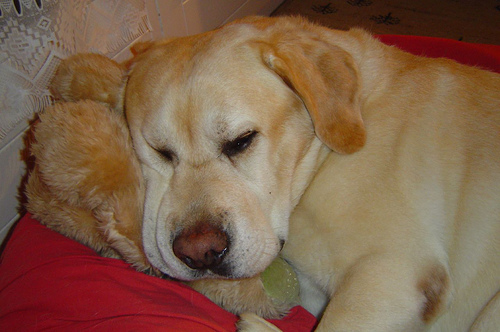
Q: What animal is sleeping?
A: Dog.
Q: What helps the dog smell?
A: Nose.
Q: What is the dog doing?
A: Sleeping.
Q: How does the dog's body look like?
A: Tan.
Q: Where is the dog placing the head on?
A: A red pillow.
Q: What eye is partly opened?
A: Left.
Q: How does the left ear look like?
A: It is dark.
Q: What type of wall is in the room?
A: Tiled.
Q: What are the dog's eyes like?
A: Dark.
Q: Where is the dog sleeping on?
A: A bed.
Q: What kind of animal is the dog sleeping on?
A: A stuffed animal.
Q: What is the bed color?
A: Red.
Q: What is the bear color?
A: Brown.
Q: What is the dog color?
A: Yellow.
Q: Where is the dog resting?
A: Bed.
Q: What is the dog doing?
A: Resting.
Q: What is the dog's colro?
A: Gold.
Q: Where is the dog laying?
A: Bed.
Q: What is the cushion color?
A: Red.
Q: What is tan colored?
A: The stuffed animal.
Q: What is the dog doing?
A: Sleeping.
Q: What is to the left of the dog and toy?
A: Red sheets.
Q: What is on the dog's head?
A: Ears.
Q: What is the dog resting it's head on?
A: A stuffed animal.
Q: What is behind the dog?
A: White wall covers.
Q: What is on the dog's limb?
A: A brown spot.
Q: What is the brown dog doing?
A: Sleeping.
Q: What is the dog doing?
A: Laying down.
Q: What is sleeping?
A: A brown dog.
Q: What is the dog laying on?
A: Stuffed toy.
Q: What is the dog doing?
A: Sleeping.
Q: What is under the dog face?
A: Stuffed toy.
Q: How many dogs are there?
A: One.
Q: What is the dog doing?
A: Laying.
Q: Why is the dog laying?
A: Rest.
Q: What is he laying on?
A: A stuffed animal.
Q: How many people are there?
A: None.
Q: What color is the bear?
A: Brown.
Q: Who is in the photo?
A: Dog.